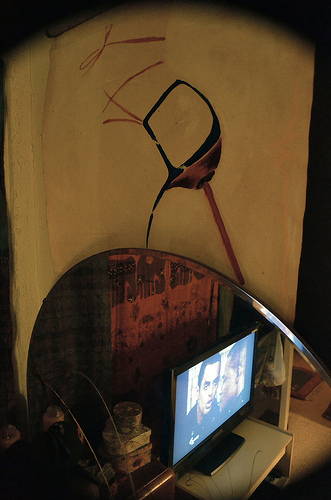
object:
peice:
[150, 82, 214, 167]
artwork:
[3, 4, 314, 431]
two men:
[186, 341, 247, 447]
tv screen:
[173, 331, 256, 467]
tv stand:
[194, 432, 245, 477]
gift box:
[102, 424, 152, 456]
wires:
[38, 371, 136, 499]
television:
[166, 322, 259, 483]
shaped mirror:
[173, 333, 256, 470]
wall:
[0, 0, 329, 440]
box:
[98, 402, 152, 476]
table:
[43, 454, 175, 500]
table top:
[175, 416, 291, 499]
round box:
[123, 469, 174, 500]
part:
[261, 262, 324, 313]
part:
[2, 249, 41, 318]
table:
[175, 416, 295, 500]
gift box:
[113, 401, 143, 436]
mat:
[286, 365, 321, 400]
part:
[40, 206, 129, 242]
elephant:
[73, 254, 205, 308]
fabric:
[26, 251, 113, 447]